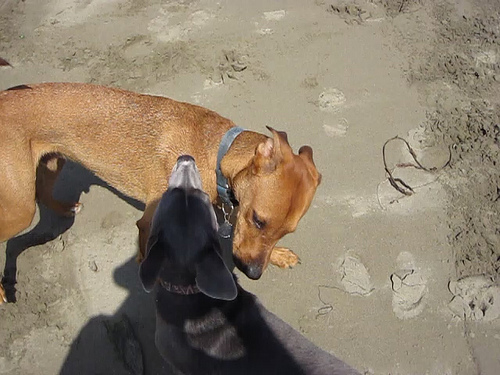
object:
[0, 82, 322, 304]
dog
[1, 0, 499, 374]
beach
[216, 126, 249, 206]
collar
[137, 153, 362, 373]
dog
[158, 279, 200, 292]
collar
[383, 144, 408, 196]
branch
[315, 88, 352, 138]
footprints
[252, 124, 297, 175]
ear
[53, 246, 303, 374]
person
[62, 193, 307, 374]
shadow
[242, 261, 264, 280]
nose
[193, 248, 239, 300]
ear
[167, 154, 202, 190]
snout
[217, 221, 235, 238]
tag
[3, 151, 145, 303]
shadow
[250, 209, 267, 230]
eye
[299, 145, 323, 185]
ear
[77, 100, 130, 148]
fur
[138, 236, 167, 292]
ear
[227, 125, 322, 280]
head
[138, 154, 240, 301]
head